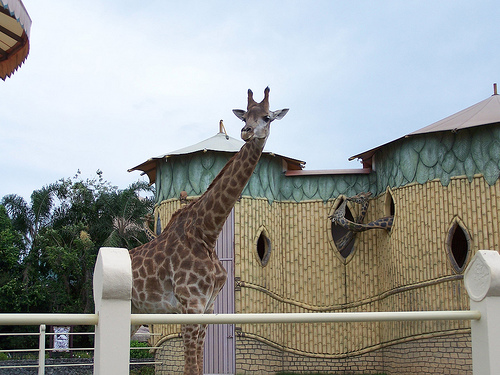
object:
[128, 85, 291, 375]
giraffe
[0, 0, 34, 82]
item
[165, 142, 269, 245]
neck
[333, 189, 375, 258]
giraffes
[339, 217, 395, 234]
necks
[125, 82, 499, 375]
house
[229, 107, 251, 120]
ear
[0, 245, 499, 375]
fence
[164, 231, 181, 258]
spots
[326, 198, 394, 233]
giraffe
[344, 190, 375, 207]
head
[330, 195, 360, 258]
window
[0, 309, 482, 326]
railing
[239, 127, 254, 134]
nose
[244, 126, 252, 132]
holes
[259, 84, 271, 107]
horns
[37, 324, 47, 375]
post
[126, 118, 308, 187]
roof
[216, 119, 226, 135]
tip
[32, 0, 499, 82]
sky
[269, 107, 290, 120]
ears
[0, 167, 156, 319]
trees